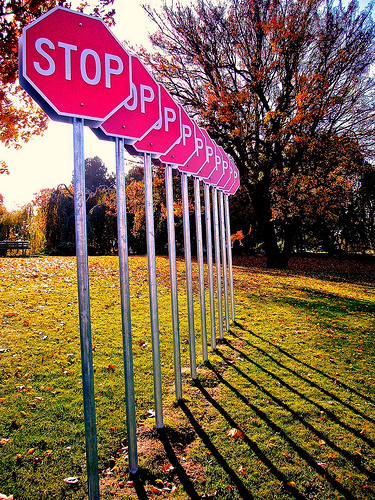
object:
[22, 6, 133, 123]
sign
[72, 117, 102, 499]
pole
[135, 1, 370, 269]
trees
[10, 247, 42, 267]
bench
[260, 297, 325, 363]
grass